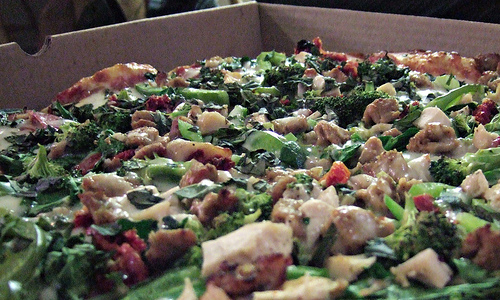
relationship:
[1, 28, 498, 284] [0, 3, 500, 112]
food in box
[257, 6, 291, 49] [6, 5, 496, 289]
shadow on box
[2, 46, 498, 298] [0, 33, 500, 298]
chicken with broccoli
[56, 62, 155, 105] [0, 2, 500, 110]
crust against box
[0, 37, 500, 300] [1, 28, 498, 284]
meat mixed in with food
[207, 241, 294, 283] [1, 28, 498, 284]
meat mixed in with food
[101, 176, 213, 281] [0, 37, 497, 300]
topping on food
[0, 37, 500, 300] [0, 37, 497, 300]
topping on food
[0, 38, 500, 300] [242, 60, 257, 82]
florets beneath cheese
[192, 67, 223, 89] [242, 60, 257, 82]
florets beneath cheese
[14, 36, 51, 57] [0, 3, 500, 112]
cutout in box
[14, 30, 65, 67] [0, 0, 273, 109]
cutout in cardboard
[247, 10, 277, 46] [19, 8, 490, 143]
corner of box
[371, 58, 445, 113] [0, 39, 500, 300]
cheese behind broccoli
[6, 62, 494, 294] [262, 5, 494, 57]
dish in box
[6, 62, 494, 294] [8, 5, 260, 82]
dish in box